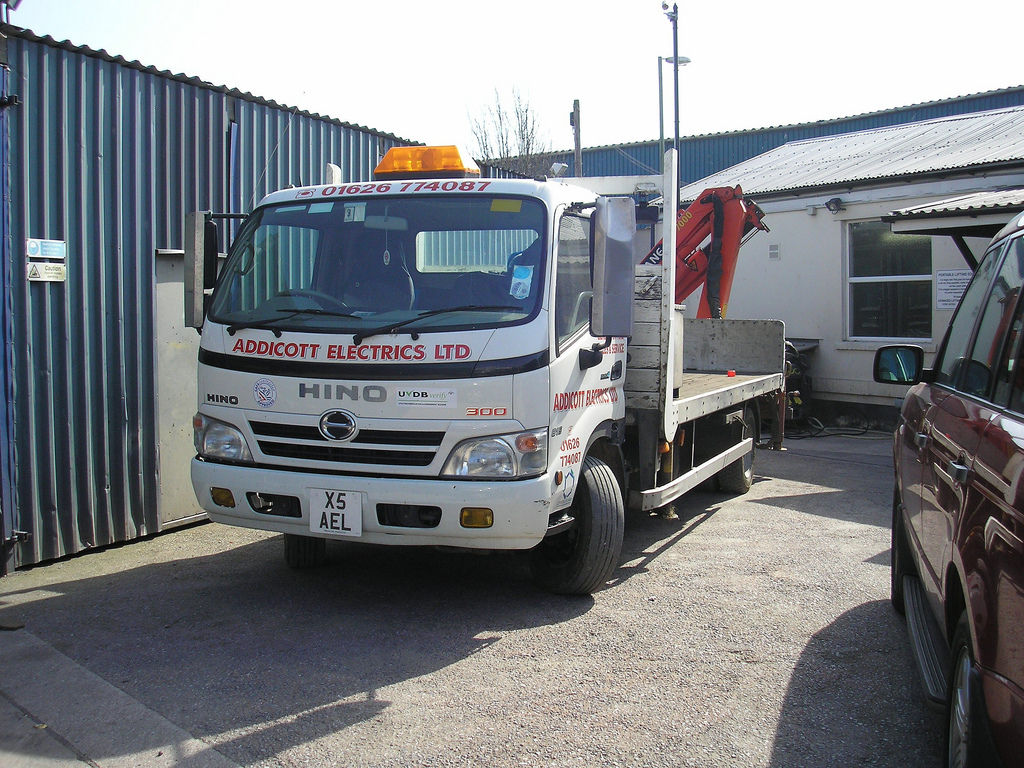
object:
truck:
[873, 206, 1023, 767]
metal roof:
[633, 104, 1023, 206]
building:
[636, 105, 1022, 433]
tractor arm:
[638, 184, 770, 319]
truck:
[191, 145, 788, 595]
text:
[232, 338, 473, 360]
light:
[373, 145, 482, 180]